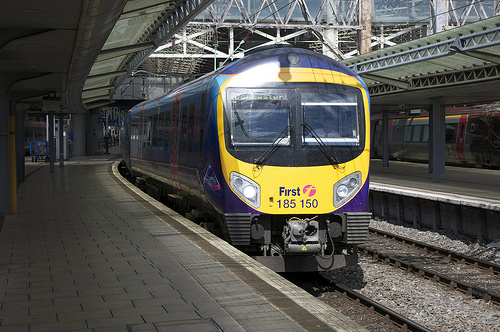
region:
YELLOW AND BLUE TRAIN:
[204, 43, 364, 253]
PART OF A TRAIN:
[108, 83, 338, 245]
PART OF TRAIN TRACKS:
[320, 217, 477, 309]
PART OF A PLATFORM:
[80, 160, 180, 294]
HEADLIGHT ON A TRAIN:
[226, 162, 272, 216]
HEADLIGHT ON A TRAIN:
[316, 163, 362, 211]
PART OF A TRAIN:
[374, 103, 481, 170]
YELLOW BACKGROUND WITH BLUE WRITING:
[262, 165, 337, 216]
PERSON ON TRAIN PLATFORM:
[97, 125, 120, 171]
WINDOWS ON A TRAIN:
[226, 84, 369, 156]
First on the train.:
[271, 181, 309, 199]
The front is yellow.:
[208, 61, 373, 233]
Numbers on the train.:
[278, 195, 326, 219]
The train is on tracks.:
[121, 23, 405, 305]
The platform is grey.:
[28, 159, 189, 330]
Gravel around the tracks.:
[339, 228, 495, 330]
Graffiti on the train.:
[463, 110, 498, 163]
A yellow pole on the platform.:
[2, 110, 25, 223]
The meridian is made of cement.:
[367, 149, 497, 232]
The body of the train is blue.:
[113, 40, 380, 218]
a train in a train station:
[99, 32, 475, 295]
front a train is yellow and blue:
[213, 43, 376, 247]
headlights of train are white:
[228, 163, 363, 212]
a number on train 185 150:
[271, 183, 326, 214]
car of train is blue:
[98, 30, 384, 245]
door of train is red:
[166, 86, 186, 178]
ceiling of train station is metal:
[7, 5, 499, 55]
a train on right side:
[377, 93, 494, 168]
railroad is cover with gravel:
[350, 230, 495, 329]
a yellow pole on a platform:
[3, 105, 23, 217]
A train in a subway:
[115, 38, 384, 270]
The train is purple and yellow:
[125, 29, 377, 263]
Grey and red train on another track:
[371, 91, 498, 171]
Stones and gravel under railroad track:
[367, 249, 473, 325]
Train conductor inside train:
[306, 109, 344, 139]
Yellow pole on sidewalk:
[2, 105, 19, 216]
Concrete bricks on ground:
[20, 207, 190, 328]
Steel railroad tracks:
[387, 222, 489, 299]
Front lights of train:
[226, 169, 368, 213]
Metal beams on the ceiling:
[214, 6, 374, 45]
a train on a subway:
[73, 63, 440, 292]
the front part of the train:
[200, 54, 377, 267]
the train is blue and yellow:
[189, 60, 391, 260]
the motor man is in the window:
[306, 103, 352, 154]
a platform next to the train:
[21, 68, 146, 259]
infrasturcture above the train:
[195, 6, 440, 41]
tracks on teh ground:
[268, 213, 486, 323]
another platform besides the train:
[392, 81, 499, 216]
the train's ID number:
[270, 180, 320, 214]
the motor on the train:
[240, 211, 366, 281]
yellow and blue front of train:
[204, 43, 377, 236]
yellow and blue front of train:
[209, 43, 385, 231]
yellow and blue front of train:
[206, 26, 383, 233]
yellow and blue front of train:
[206, 36, 383, 248]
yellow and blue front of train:
[220, 40, 386, 248]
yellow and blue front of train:
[209, 38, 391, 234]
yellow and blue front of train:
[207, 42, 383, 239]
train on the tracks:
[110, 40, 397, 277]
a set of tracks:
[382, 215, 491, 326]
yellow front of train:
[216, 77, 370, 214]